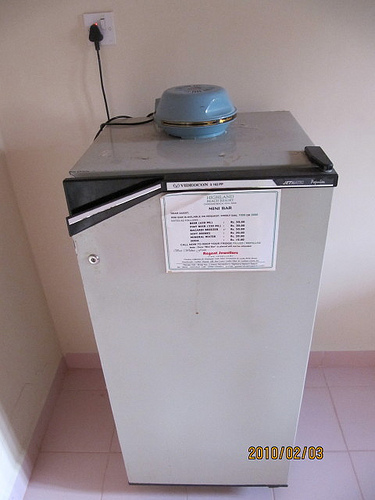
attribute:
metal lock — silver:
[83, 252, 103, 268]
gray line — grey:
[34, 444, 109, 459]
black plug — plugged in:
[85, 23, 101, 52]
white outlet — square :
[83, 12, 116, 50]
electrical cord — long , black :
[86, 25, 153, 135]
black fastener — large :
[305, 142, 334, 171]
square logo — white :
[160, 188, 280, 275]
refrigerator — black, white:
[59, 109, 334, 491]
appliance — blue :
[145, 80, 242, 137]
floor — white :
[34, 446, 104, 497]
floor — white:
[44, 373, 373, 494]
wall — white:
[1, 4, 361, 372]